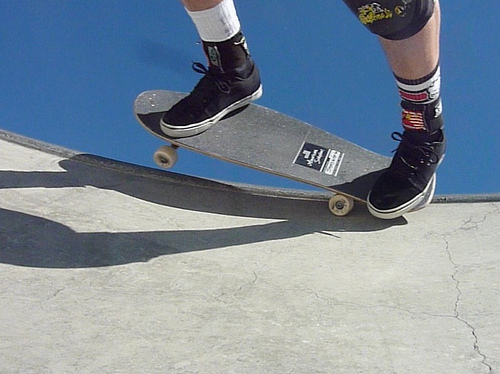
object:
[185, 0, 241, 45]
sock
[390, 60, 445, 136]
sock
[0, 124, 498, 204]
ledge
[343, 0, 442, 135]
legs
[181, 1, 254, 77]
legs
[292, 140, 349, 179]
sticker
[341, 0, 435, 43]
knee pad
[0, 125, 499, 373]
ramp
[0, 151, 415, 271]
shadow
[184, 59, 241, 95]
shoe laces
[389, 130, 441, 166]
shoe laces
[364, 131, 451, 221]
foot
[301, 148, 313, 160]
design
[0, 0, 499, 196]
sky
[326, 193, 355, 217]
wheel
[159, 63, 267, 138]
sole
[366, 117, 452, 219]
shoe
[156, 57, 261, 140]
foot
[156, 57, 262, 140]
shoe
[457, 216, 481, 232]
patch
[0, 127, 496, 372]
concrete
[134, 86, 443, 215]
skateboard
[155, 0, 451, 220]
man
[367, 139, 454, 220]
sole